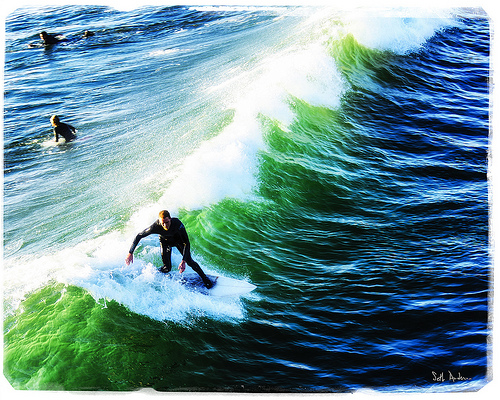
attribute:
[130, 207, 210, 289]
man — surfing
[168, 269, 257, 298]
surfboard — white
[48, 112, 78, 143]
boy — swimming away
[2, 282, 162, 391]
ocean — green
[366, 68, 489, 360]
ocean — dark blue, blue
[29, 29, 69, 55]
man — surfing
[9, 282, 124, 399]
water — green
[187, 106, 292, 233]
water — green, splashing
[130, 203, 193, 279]
surfer — blond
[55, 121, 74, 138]
wetsuit — black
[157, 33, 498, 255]
ocean — blue, green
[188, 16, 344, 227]
wave crest — white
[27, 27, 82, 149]
people — surfing